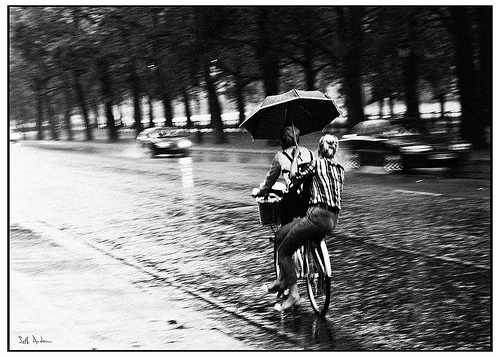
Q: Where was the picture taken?
A: It was taken at the road.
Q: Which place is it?
A: It is a road.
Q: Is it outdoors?
A: Yes, it is outdoors.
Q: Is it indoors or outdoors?
A: It is outdoors.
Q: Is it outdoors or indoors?
A: It is outdoors.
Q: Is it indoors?
A: No, it is outdoors.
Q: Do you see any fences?
A: No, there are no fences.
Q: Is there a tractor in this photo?
A: No, there are no tractors.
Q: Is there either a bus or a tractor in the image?
A: No, there are no tractors or buses.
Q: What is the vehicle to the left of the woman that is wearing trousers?
A: The vehicle is a car.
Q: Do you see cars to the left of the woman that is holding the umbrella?
A: Yes, there is a car to the left of the woman.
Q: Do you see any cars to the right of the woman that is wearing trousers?
A: No, the car is to the left of the woman.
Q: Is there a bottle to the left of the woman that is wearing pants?
A: No, there is a car to the left of the woman.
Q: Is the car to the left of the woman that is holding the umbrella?
A: Yes, the car is to the left of the woman.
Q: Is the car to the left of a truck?
A: No, the car is to the left of the woman.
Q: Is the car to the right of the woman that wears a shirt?
A: No, the car is to the left of the woman.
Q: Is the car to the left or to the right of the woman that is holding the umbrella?
A: The car is to the left of the woman.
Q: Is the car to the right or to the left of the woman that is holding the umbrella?
A: The car is to the left of the woman.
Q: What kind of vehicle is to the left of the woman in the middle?
A: The vehicle is a car.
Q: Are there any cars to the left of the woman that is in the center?
A: Yes, there is a car to the left of the woman.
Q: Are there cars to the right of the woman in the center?
A: No, the car is to the left of the woman.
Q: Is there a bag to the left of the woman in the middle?
A: No, there is a car to the left of the woman.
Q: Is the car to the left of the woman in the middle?
A: Yes, the car is to the left of the woman.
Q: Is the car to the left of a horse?
A: No, the car is to the left of the woman.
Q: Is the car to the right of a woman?
A: No, the car is to the left of a woman.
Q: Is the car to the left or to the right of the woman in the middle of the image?
A: The car is to the left of the woman.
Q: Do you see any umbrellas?
A: Yes, there is an umbrella.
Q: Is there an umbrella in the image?
A: Yes, there is an umbrella.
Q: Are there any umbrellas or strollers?
A: Yes, there is an umbrella.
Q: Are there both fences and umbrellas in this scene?
A: No, there is an umbrella but no fences.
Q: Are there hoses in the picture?
A: No, there are no hoses.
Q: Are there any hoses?
A: No, there are no hoses.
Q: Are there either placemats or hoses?
A: No, there are no hoses or placemats.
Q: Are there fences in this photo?
A: No, there are no fences.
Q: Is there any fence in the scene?
A: No, there are no fences.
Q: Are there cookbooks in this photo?
A: No, there are no cookbooks.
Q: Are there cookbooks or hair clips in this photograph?
A: No, there are no cookbooks or hair clips.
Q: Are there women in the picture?
A: Yes, there is a woman.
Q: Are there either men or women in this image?
A: Yes, there is a woman.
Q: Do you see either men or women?
A: Yes, there is a woman.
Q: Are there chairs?
A: No, there are no chairs.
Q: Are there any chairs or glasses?
A: No, there are no chairs or glasses.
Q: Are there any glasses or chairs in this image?
A: No, there are no chairs or glasses.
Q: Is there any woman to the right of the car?
A: Yes, there is a woman to the right of the car.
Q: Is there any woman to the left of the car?
A: No, the woman is to the right of the car.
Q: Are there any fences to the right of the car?
A: No, there is a woman to the right of the car.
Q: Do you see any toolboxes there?
A: No, there are no toolboxes.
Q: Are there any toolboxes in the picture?
A: No, there are no toolboxes.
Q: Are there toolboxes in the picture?
A: No, there are no toolboxes.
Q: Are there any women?
A: Yes, there is a woman.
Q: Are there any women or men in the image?
A: Yes, there is a woman.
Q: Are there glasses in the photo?
A: No, there are no glasses.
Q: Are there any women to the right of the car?
A: Yes, there is a woman to the right of the car.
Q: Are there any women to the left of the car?
A: No, the woman is to the right of the car.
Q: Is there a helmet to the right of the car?
A: No, there is a woman to the right of the car.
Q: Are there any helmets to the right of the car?
A: No, there is a woman to the right of the car.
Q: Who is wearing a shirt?
A: The woman is wearing a shirt.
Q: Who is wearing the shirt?
A: The woman is wearing a shirt.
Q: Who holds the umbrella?
A: The woman holds the umbrella.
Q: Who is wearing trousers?
A: The woman is wearing trousers.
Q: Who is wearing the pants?
A: The woman is wearing trousers.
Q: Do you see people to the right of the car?
A: Yes, there are people to the right of the car.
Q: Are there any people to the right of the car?
A: Yes, there are people to the right of the car.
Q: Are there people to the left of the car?
A: No, the people are to the right of the car.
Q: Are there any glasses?
A: No, there are no glasses.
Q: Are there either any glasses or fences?
A: No, there are no glasses or fences.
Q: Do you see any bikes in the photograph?
A: Yes, there is a bike.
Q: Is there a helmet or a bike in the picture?
A: Yes, there is a bike.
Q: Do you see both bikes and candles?
A: No, there is a bike but no candles.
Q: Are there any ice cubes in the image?
A: No, there are no ice cubes.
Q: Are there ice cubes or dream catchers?
A: No, there are no ice cubes or dream catchers.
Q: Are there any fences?
A: No, there are no fences.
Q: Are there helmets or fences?
A: No, there are no fences or helmets.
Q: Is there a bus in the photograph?
A: No, there are no buses.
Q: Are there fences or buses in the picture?
A: No, there are no buses or fences.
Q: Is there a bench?
A: No, there are no benches.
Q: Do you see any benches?
A: No, there are no benches.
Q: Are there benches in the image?
A: No, there are no benches.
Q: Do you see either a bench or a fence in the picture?
A: No, there are no benches or fences.